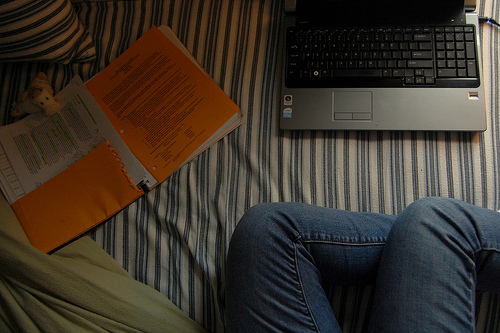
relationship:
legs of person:
[224, 195, 500, 332] [0, 193, 500, 331]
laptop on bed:
[280, 1, 485, 135] [1, 0, 499, 332]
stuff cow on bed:
[9, 71, 61, 118] [1, 0, 499, 332]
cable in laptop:
[480, 17, 499, 31] [280, 1, 485, 135]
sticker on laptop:
[284, 94, 294, 106] [280, 1, 485, 135]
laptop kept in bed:
[280, 1, 485, 135] [1, 0, 499, 332]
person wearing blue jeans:
[0, 193, 500, 331] [222, 199, 495, 332]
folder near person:
[0, 27, 243, 253] [0, 193, 500, 331]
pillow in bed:
[1, 1, 97, 67] [1, 0, 499, 332]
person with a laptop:
[0, 193, 500, 331] [280, 1, 485, 135]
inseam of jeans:
[291, 234, 382, 330] [222, 199, 495, 332]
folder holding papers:
[0, 27, 243, 253] [2, 77, 148, 199]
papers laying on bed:
[2, 77, 148, 199] [1, 0, 499, 332]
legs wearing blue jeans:
[224, 195, 500, 332] [222, 199, 495, 332]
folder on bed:
[0, 27, 243, 253] [1, 0, 499, 332]